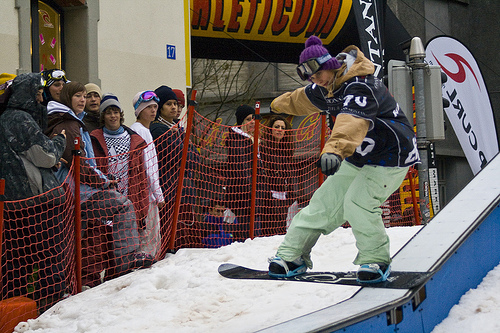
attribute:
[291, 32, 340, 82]
bonnet — purple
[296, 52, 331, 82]
goggles — blue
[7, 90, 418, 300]
fence — snow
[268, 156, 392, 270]
pants — green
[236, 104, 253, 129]
hat — black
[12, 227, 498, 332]
snow — white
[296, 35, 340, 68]
hat — purple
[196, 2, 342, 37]
sign — red, white, black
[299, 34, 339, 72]
hat — purple, knit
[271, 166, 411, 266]
pants — green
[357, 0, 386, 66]
sign — black, white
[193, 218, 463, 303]
snowboard — black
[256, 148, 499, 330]
ramp — white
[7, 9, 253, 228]
wall — white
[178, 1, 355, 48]
sign — red